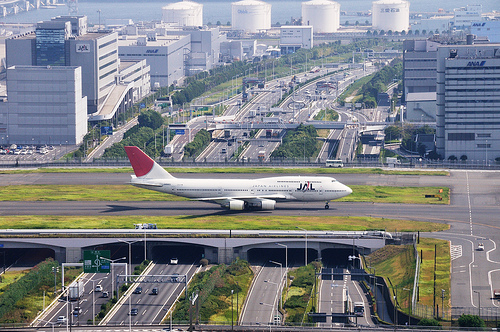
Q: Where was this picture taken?
A: Airport.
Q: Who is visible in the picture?
A: No one.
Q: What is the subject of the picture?
A: Airplane.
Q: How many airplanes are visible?
A: One.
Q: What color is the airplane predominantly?
A: White.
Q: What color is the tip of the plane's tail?
A: Red.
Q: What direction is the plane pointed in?
A: Right.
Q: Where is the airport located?
A: City.